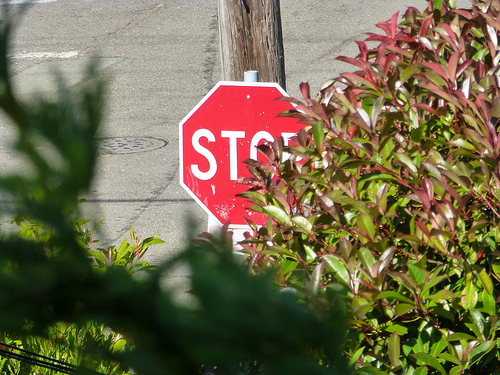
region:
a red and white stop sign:
[168, 60, 341, 267]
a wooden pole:
[193, 2, 311, 94]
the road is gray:
[10, 5, 229, 279]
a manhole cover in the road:
[74, 115, 186, 179]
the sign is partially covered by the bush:
[175, 17, 497, 355]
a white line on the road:
[1, 31, 105, 94]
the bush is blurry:
[6, 10, 355, 369]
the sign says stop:
[138, 61, 343, 262]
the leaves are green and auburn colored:
[215, 0, 497, 367]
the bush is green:
[3, 195, 201, 372]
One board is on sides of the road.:
[177, 90, 325, 225]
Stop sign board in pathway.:
[168, 81, 349, 251]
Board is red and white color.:
[178, 101, 320, 242]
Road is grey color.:
[107, 170, 174, 240]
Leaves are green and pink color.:
[322, 90, 472, 246]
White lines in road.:
[7, 37, 122, 92]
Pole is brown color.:
[216, 16, 304, 73]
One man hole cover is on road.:
[91, 122, 166, 173]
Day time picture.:
[30, 27, 486, 368]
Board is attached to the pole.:
[198, 61, 305, 276]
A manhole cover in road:
[59, 121, 174, 170]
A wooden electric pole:
[213, 1, 297, 72]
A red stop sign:
[178, 76, 334, 236]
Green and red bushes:
[332, 14, 498, 373]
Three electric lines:
[1, 340, 117, 373]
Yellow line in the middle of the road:
[106, 0, 185, 42]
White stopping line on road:
[0, 42, 81, 64]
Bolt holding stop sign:
[229, 89, 264, 106]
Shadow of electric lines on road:
[78, 193, 188, 205]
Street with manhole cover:
[6, 6, 179, 237]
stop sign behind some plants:
[164, 70, 341, 231]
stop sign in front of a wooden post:
[166, 61, 331, 253]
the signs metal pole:
[237, 61, 265, 272]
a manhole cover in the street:
[53, 116, 175, 168]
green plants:
[237, 60, 495, 339]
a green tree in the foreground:
[3, 49, 160, 323]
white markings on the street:
[2, 33, 128, 69]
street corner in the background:
[21, 23, 206, 165]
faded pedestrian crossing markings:
[6, 33, 138, 116]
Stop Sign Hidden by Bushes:
[35, 53, 441, 313]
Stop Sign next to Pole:
[160, 49, 353, 263]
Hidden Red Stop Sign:
[164, 52, 340, 262]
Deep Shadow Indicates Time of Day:
[6, 8, 370, 373]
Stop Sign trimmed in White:
[173, 58, 333, 269]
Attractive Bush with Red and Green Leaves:
[237, 8, 495, 369]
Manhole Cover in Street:
[89, 111, 170, 166]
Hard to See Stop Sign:
[22, 23, 483, 360]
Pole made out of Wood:
[184, 5, 325, 69]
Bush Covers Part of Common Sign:
[170, 60, 341, 272]